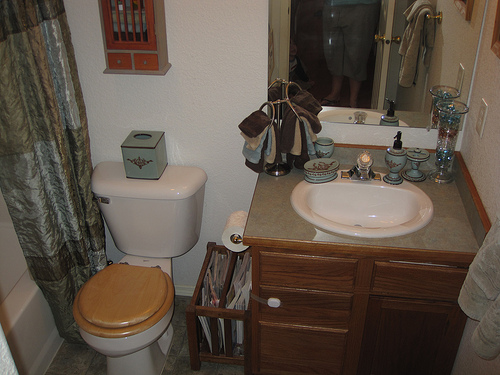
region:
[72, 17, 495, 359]
the scene is in a bathroom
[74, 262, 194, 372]
the toilet seat is brown in colour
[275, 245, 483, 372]
the drawer is brown in colour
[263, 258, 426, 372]
the drawer is wooden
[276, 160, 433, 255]
the sink is white in colour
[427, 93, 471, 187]
a large glass object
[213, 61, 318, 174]
socks are hanged in a rack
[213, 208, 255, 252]
a white tissue roll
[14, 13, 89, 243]
a brown and grey curtain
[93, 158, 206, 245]
a white water tank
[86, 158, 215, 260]
the water tank is white in colour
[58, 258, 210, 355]
the cover is brown in colour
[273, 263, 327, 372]
the drawer is wooden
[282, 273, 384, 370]
it is brown in colour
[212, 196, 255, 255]
the toilet roll is white in colour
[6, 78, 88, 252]
the curtain has patterns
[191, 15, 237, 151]
the wall is white in colour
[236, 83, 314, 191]
socks are hanged in the rack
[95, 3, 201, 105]
the drawer is brown and white in colour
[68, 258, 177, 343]
Brown wooden toilet seat lid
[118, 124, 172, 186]
A box of tissues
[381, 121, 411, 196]
Hand soap on sink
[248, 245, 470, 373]
Brown wooden drawers and cabinet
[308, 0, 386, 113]
Person's reflection in mirror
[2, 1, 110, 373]
Shower curtain in front of bathtub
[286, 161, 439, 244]
Oval shaped white sink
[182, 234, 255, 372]
Many magazines in a rack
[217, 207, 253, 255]
A roll of toilet paper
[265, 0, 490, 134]
A mirror on the wall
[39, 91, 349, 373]
a white bathroom toilet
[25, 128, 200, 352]
a white toilet with brown lid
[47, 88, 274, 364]
white toilet with brown seat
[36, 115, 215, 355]
a tissue box on top of toilet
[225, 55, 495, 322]
a towel holder on the counter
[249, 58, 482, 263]
handclothes on towel holder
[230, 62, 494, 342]
a bathroom counter with sink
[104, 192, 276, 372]
a wooden magazine rack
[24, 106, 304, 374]
a magazine rack next to toilet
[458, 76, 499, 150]
an electrical plug on the wall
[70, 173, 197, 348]
toilet with wooden seat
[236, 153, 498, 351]
wood cabinet under sink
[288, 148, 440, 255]
white sink on granite top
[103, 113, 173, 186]
green tissue box on tank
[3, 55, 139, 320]
dark shower curtain on left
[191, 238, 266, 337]
rack of newspapers by toilet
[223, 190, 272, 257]
white toilet paper roll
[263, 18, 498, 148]
bathroom mirror over sink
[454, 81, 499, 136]
white electric outlet on wall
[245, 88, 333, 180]
small bag on sink